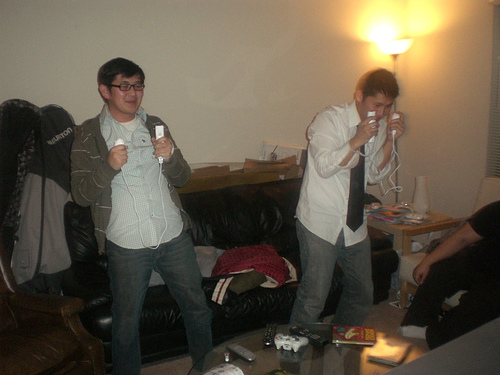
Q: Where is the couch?
A: Behind the boys.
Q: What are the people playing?
A: Wii.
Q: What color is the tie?
A: Black.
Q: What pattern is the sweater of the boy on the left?
A: Striped.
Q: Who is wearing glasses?
A: Boy on the left.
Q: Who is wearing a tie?
A: Boy on the right.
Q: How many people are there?
A: 3.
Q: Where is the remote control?
A: On the table.